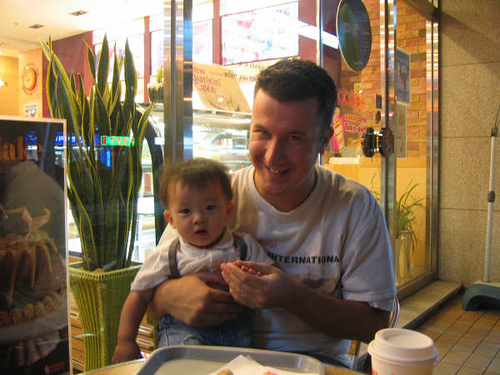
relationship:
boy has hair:
[140, 161, 280, 339] [164, 160, 227, 180]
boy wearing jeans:
[140, 161, 280, 339] [153, 314, 261, 350]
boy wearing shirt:
[140, 161, 280, 339] [128, 233, 271, 274]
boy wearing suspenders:
[140, 161, 280, 339] [171, 237, 251, 265]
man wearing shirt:
[209, 40, 421, 374] [230, 164, 402, 359]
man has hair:
[209, 40, 421, 374] [265, 53, 324, 104]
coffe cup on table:
[361, 316, 442, 373] [71, 337, 407, 374]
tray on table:
[142, 343, 323, 373] [71, 337, 407, 374]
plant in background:
[43, 43, 146, 289] [10, 2, 250, 168]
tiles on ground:
[470, 329, 493, 363] [416, 284, 499, 373]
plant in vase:
[43, 43, 146, 289] [65, 254, 133, 367]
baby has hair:
[140, 161, 280, 339] [164, 160, 227, 180]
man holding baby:
[209, 40, 421, 374] [140, 161, 280, 339]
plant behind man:
[43, 43, 146, 289] [209, 40, 421, 374]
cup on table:
[361, 316, 442, 373] [71, 337, 407, 374]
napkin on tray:
[224, 352, 267, 373] [142, 343, 323, 373]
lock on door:
[371, 126, 399, 160] [329, 1, 449, 288]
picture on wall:
[22, 101, 42, 114] [20, 53, 51, 118]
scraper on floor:
[455, 116, 499, 318] [416, 284, 499, 373]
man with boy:
[209, 40, 421, 374] [140, 161, 280, 339]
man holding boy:
[209, 40, 421, 374] [140, 161, 280, 339]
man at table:
[209, 40, 421, 374] [71, 337, 407, 374]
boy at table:
[140, 161, 280, 339] [71, 337, 407, 374]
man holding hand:
[209, 40, 421, 374] [224, 260, 263, 276]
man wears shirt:
[209, 40, 421, 374] [230, 164, 402, 359]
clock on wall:
[19, 64, 39, 91] [20, 53, 51, 118]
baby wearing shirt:
[140, 161, 280, 339] [128, 233, 271, 274]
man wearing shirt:
[209, 40, 421, 374] [128, 233, 271, 274]